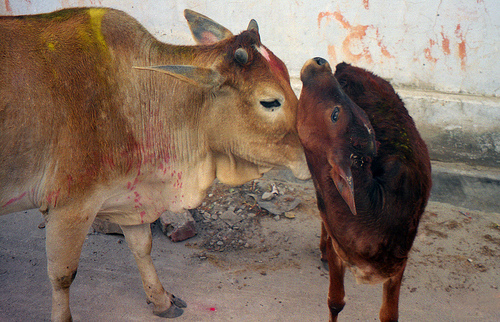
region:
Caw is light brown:
[5, 2, 312, 317]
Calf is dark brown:
[288, 47, 423, 317]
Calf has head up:
[289, 40, 439, 320]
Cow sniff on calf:
[5, 1, 322, 319]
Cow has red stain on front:
[256, 39, 285, 79]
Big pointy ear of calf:
[321, 151, 369, 222]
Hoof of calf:
[152, 289, 193, 319]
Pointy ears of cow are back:
[127, 1, 237, 97]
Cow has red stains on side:
[94, 103, 192, 239]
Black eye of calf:
[321, 98, 344, 127]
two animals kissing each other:
[158, 29, 353, 209]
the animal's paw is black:
[155, 295, 195, 320]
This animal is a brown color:
[291, 86, 450, 295]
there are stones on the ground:
[204, 196, 276, 268]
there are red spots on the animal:
[45, 114, 190, 241]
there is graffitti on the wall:
[340, 8, 458, 65]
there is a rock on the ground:
[160, 213, 185, 241]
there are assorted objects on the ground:
[253, 178, 294, 231]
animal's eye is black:
[260, 98, 275, 113]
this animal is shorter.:
[303, 56, 452, 319]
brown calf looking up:
[295, 53, 382, 178]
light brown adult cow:
[171, 1, 298, 201]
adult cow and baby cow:
[195, 7, 380, 223]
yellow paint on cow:
[20, 7, 140, 92]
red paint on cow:
[95, 112, 201, 238]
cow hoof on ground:
[135, 290, 195, 316]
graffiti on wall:
[295, 0, 491, 85]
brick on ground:
[155, 205, 196, 255]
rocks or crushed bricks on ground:
[211, 175, 302, 255]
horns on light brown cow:
[227, 13, 262, 73]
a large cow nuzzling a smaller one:
[1, 5, 324, 310]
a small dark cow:
[295, 46, 445, 320]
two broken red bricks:
[71, 173, 205, 260]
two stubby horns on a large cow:
[224, 13, 269, 75]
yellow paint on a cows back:
[34, 0, 138, 114]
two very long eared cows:
[3, 7, 430, 319]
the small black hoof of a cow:
[142, 282, 192, 319]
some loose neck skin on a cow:
[51, 134, 296, 250]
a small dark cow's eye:
[328, 98, 346, 129]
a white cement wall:
[4, 3, 499, 223]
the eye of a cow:
[255, 93, 286, 110]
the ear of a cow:
[131, 50, 226, 92]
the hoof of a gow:
[142, 285, 189, 319]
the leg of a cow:
[41, 191, 111, 320]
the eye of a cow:
[329, 99, 348, 123]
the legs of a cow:
[322, 240, 419, 320]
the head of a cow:
[291, 51, 380, 220]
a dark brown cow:
[291, 55, 436, 320]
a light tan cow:
[1, 5, 311, 320]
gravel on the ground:
[87, 174, 314, 274]